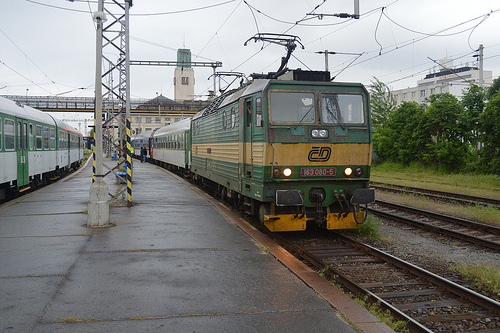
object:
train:
[133, 69, 373, 234]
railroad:
[311, 245, 499, 324]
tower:
[172, 47, 196, 103]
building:
[133, 95, 216, 135]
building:
[369, 47, 497, 122]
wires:
[239, 1, 499, 62]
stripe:
[189, 141, 373, 166]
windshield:
[266, 89, 366, 125]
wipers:
[295, 99, 318, 128]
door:
[240, 96, 252, 175]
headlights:
[283, 167, 293, 178]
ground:
[0, 211, 226, 331]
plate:
[303, 167, 338, 178]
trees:
[384, 77, 499, 178]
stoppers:
[262, 208, 367, 233]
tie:
[370, 288, 447, 299]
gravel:
[410, 234, 465, 263]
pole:
[124, 117, 133, 206]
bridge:
[3, 95, 214, 118]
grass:
[463, 260, 496, 283]